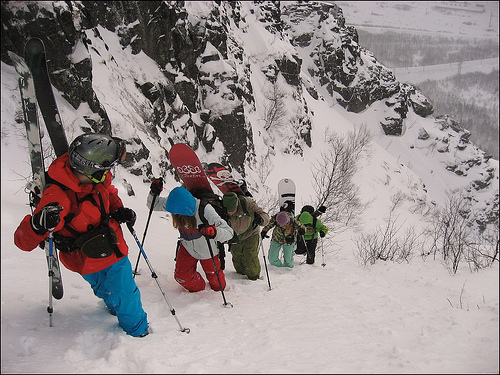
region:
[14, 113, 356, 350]
People treking up mountain with snow skis and snowboards.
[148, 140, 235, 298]
Woman carrying snowboard on her back.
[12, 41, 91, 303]
Person carrying snow skis on back.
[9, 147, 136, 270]
Person dressed in red jacket.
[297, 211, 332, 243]
Person wearing green jacket.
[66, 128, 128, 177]
Person wearing gray safety helmet.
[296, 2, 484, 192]
Rocks covered in snow on side of mountain.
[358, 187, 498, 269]
Bare branches sticking out of snow.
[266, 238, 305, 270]
Person dressed in light green pants.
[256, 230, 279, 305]
Person holding ski pole in hand.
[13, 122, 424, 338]
skiers scale a steep mountain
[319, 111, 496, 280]
leafless brush along the hiking trail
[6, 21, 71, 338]
pair of black skies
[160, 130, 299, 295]
three skier carry snowboards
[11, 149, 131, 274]
a red snow parka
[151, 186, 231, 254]
a blue hood worn under a white parka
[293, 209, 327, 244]
bright green hooded jacket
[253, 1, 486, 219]
snow covered rocky mountain side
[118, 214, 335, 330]
skiers all carry ski poles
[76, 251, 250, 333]
a pair of blue snow pants and a pair of red.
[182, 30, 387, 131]
a view of mountains are covered with snow.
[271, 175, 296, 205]
a white and black ski board.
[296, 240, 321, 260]
a man is wearing black pants.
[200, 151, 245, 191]
a black and red ski board.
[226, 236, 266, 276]
a man is wearing green pants.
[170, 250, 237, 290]
a woman is wearing red pants.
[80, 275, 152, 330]
a man is wearing blue pants.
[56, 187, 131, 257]
a man is wearing a red coat.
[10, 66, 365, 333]
a bunch of people are going skiing.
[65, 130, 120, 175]
a man is wearing a black helmet.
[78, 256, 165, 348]
a pair of blue ski pants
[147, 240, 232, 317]
a pair of red ski pants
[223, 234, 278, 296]
a pair of green ski pants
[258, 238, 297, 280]
a pair of blue ski pants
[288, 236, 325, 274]
a pair of black ski pants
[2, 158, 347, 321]
five people getting reday to snowboard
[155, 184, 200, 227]
a blue hoodie and long hair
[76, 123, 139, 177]
a silver helmet and goggles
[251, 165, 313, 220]
a black and white snowboard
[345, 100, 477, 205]
snow on a rocky mountain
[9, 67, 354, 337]
five skiers climbing up a snow slope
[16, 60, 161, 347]
skier wearing a red coat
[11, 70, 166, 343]
skier wearing blue pants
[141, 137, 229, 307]
skier wearing red pants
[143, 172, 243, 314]
skier wearing a light grey coat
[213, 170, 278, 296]
skier wearing green pants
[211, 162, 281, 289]
skier wearing a tan coat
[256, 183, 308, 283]
skier wearing green pants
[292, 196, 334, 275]
skier wearing a green coat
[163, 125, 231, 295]
skier carrying a red snowboard